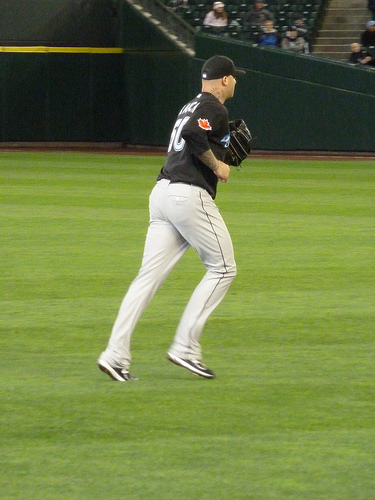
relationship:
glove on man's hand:
[228, 116, 255, 166] [228, 117, 253, 166]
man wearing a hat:
[96, 51, 253, 383] [196, 50, 247, 84]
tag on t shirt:
[195, 116, 218, 134] [156, 90, 229, 199]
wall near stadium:
[1, 1, 372, 153] [1, 0, 372, 497]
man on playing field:
[96, 51, 253, 383] [1, 145, 373, 496]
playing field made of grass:
[1, 145, 373, 496] [1, 148, 374, 500]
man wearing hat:
[96, 51, 253, 383] [196, 50, 247, 84]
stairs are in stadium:
[133, 0, 197, 55] [1, 0, 372, 497]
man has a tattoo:
[96, 51, 253, 383] [209, 81, 227, 102]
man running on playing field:
[96, 51, 253, 383] [1, 145, 373, 496]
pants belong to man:
[101, 180, 243, 372] [96, 51, 253, 383]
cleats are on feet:
[96, 346, 216, 388] [96, 351, 218, 385]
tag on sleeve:
[195, 116, 218, 134] [180, 103, 222, 158]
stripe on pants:
[198, 187, 232, 348] [101, 180, 243, 372]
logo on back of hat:
[200, 69, 212, 81] [196, 50, 247, 84]